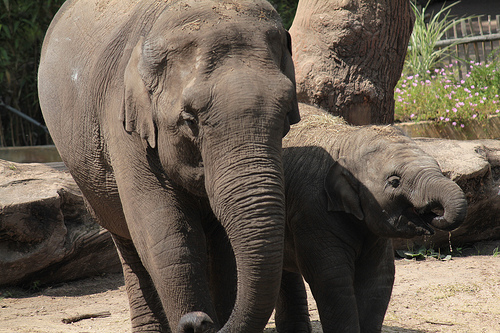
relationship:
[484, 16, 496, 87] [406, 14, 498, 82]
post of fence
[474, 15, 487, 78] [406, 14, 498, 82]
post of fence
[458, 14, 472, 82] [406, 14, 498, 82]
post of fence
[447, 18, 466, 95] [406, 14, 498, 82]
post of fence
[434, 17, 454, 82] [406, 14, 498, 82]
post of fence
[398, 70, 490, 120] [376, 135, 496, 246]
wildflowers behind wall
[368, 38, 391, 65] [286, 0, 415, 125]
bark on tree trunk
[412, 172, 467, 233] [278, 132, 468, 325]
trunk of elephant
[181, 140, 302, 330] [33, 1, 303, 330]
trunk of elephant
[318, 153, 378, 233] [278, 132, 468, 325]
ear of elephant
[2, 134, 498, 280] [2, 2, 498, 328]
wall in enclosure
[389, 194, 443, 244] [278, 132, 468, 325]
mouth of elephant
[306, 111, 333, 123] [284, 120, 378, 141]
hay on back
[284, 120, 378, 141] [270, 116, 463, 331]
back of elephant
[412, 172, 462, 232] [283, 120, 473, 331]
trunk of elephant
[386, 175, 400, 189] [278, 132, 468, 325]
eye of elephant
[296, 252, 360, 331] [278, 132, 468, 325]
leg of elephant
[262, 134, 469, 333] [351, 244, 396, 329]
baby elephant has leg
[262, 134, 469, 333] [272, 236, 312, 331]
baby elephant has leg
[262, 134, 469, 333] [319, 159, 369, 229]
baby elephant has ear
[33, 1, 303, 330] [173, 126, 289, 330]
elephant has trunk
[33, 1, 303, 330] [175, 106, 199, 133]
elephant has eye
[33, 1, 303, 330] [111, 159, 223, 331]
elephant has leg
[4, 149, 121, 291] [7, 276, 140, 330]
rock sitting on ground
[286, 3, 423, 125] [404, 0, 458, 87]
tree trunk has foilage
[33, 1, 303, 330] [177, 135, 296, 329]
elephant has trunk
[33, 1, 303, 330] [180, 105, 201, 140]
elephant has eye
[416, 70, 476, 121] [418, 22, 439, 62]
flowers near tree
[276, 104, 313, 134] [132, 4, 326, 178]
eye on head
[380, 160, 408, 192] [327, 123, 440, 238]
eye on head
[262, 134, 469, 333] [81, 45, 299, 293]
baby elephant to right of elephant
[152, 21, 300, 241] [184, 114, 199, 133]
head has an eye